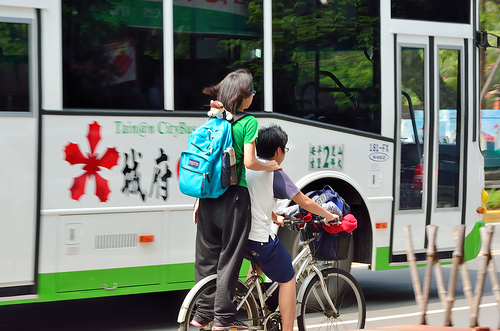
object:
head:
[253, 123, 291, 164]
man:
[244, 123, 339, 331]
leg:
[264, 244, 300, 331]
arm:
[275, 170, 335, 218]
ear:
[275, 146, 282, 156]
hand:
[323, 214, 341, 227]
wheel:
[290, 266, 376, 331]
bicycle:
[173, 214, 368, 331]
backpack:
[174, 116, 240, 201]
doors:
[387, 31, 470, 265]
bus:
[0, 0, 491, 310]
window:
[57, 0, 169, 112]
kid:
[177, 66, 284, 331]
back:
[240, 158, 275, 237]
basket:
[305, 218, 351, 261]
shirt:
[225, 112, 265, 188]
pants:
[188, 194, 254, 316]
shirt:
[238, 153, 306, 237]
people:
[186, 65, 340, 331]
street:
[294, 266, 500, 325]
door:
[0, 4, 49, 302]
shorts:
[240, 236, 298, 285]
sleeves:
[271, 169, 301, 200]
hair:
[252, 123, 296, 159]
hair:
[203, 69, 258, 117]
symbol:
[60, 120, 121, 203]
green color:
[0, 259, 262, 305]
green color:
[44, 272, 174, 289]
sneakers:
[188, 312, 250, 331]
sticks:
[396, 222, 499, 326]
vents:
[91, 232, 138, 251]